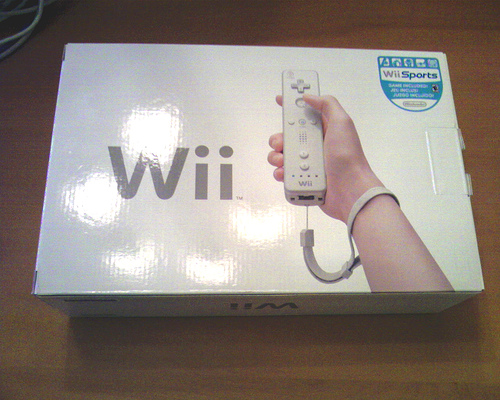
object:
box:
[29, 40, 485, 318]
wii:
[106, 143, 235, 203]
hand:
[266, 94, 382, 222]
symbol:
[106, 145, 234, 201]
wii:
[382, 70, 439, 83]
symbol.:
[381, 68, 438, 80]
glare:
[119, 108, 179, 159]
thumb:
[299, 93, 355, 137]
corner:
[0, 0, 54, 59]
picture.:
[0, 0, 497, 400]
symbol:
[228, 299, 301, 313]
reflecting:
[122, 107, 183, 165]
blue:
[376, 54, 444, 111]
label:
[375, 54, 444, 114]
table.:
[1, 0, 499, 400]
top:
[0, 1, 57, 62]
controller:
[280, 67, 328, 206]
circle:
[294, 96, 309, 109]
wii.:
[280, 68, 329, 206]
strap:
[301, 183, 403, 282]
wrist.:
[327, 169, 401, 238]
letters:
[106, 145, 191, 197]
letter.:
[216, 145, 235, 202]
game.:
[107, 144, 234, 202]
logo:
[106, 144, 236, 201]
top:
[281, 69, 324, 129]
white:
[281, 69, 328, 207]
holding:
[267, 94, 381, 221]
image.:
[268, 68, 365, 224]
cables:
[1, 0, 60, 61]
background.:
[0, 0, 56, 62]